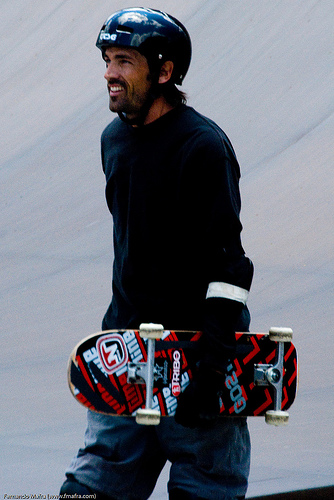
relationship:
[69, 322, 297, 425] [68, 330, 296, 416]
skateboard full of colors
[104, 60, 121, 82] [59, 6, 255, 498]
nose on man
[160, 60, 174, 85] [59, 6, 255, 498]
ear on man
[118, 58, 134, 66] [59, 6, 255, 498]
eye on man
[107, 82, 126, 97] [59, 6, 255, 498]
mouth on man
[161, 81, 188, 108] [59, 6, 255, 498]
hair on man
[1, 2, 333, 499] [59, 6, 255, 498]
half pipe behind man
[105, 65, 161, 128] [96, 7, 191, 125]
strap under helmet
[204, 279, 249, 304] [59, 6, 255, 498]
stripe on man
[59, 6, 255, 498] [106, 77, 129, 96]
man has mustache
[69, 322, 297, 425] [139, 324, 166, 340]
skateboard has a wheel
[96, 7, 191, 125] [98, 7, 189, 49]
helmet has light reflecting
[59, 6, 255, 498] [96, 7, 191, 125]
man wearing a helmet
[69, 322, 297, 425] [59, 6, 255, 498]
skateboard being held by man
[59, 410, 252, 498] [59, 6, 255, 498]
jeans on man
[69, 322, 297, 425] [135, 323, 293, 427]
skateboard has wheels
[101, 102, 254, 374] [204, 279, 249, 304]
shirt has a stripe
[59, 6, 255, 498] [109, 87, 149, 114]
man has a beard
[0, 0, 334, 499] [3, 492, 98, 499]
photo has words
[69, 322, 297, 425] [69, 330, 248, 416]
skateboard has words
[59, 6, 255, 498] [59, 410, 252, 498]
man wearing jeans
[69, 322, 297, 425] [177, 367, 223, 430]
skateboard in mans hand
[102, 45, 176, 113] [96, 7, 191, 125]
head has a helmet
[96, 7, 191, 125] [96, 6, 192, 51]
helmet has a shine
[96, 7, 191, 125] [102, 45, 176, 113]
helmet on mans head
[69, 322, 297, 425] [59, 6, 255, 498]
skateboard being carried by man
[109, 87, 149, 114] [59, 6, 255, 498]
beard on man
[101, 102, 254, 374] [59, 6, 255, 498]
shirt on man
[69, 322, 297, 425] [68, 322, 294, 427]
skateboard has white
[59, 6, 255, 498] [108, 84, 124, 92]
man has white teeth